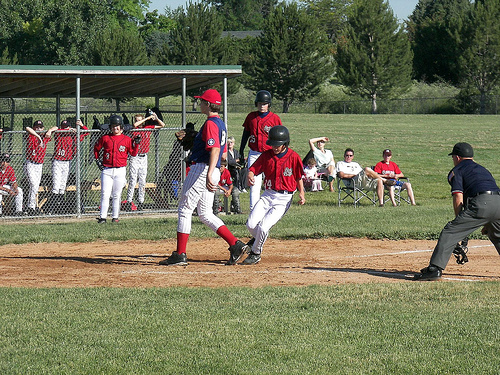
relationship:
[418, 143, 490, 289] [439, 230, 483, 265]
player with mitt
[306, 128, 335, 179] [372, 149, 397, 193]
woman and ki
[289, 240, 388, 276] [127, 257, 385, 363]
dirt on field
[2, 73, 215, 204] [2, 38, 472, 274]
spectators in background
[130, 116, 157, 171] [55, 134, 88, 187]
person behind fence